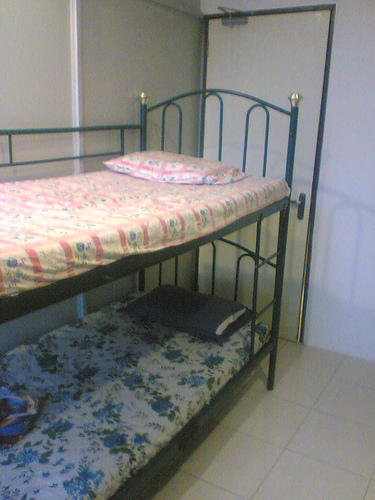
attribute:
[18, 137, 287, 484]
bunk bed — metal-framed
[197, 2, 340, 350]
bedroom door — cream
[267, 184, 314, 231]
door lever — silver door  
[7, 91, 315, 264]
bed — patterned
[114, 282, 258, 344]
pillow — blue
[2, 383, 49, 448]
blanket — bunched up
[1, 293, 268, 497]
bed — bottom 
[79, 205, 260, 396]
bunk beds — metal bunk, dark blue 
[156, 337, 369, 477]
floor — off white colored linoleum tiled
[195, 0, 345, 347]
door — metal self closing door 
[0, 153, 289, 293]
sheet — white, blue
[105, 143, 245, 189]
pillow case — white